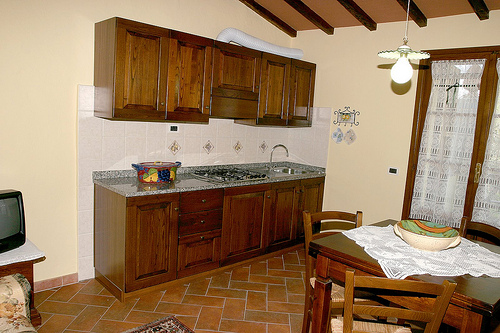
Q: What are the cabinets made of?
A: Wood.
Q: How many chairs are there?
A: Three.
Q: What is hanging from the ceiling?
A: The light.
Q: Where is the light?
A: Hanging from the ceiling.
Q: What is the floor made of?
A: Tile.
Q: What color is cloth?
A: White.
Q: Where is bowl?
A: On table.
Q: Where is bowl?
A: On table.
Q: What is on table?
A: Bowl.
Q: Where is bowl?
A: On table.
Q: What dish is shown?
A: Bowl.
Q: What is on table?
A: Bowl.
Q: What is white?
A: Table cloth.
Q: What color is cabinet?
A: Brown.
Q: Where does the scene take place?
A: In a kitchen.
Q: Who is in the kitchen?
A: No one.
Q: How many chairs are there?
A: Three.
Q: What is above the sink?
A: Cabinets.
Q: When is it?
A: Daytime.